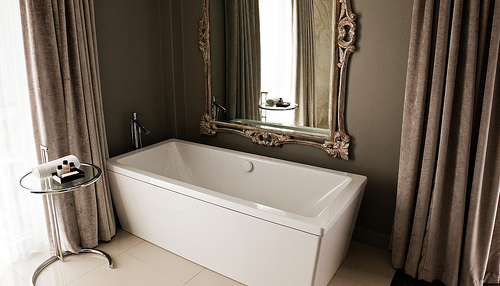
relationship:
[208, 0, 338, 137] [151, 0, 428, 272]
hanging mirror on wall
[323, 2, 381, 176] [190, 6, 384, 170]
frame on mirror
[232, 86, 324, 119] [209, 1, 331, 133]
reflection in mirror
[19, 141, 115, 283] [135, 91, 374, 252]
table near tub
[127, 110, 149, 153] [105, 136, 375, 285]
fixture on tub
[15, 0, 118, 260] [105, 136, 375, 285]
curtain hanging near tub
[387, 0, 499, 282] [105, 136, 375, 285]
curtain hanging near tub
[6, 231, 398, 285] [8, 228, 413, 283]
tiles on floor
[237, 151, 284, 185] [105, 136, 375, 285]
drain of tub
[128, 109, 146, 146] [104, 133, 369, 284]
faucet of bathtub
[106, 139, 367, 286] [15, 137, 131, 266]
bathtub accessories on table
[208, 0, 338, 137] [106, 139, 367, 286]
hanging mirror above bathtub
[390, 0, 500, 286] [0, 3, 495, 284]
curtain in a bathroom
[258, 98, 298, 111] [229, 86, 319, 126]
reflection on table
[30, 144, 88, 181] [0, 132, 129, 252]
towel on table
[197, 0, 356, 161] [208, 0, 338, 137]
frame on hanging mirror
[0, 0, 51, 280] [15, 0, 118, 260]
window next to curtain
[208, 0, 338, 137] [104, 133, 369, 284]
hanging mirror above bathtub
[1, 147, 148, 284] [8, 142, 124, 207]
small table with glass top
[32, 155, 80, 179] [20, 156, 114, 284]
towel on table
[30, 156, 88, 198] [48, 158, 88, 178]
small bottles of shampoo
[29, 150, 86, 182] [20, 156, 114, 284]
contents are on table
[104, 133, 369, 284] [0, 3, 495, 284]
bathtub in bathroom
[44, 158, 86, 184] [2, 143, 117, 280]
toiletries are on table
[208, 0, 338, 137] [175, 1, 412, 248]
hanging mirror hanging on wall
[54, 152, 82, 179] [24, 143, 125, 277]
objects are on end table